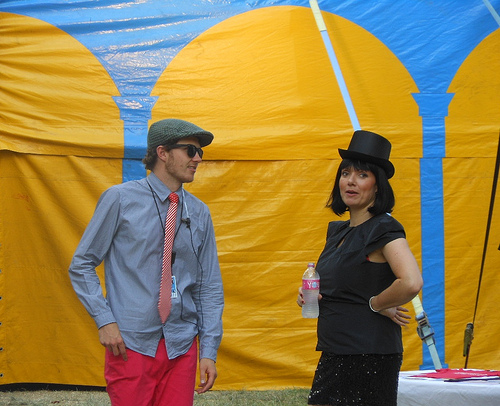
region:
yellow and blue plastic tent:
[1, 0, 499, 392]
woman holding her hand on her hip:
[295, 127, 425, 404]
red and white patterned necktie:
[156, 191, 180, 327]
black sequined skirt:
[306, 349, 405, 404]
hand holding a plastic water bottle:
[296, 260, 324, 320]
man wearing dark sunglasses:
[63, 116, 227, 403]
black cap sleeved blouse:
[312, 213, 409, 353]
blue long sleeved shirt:
[63, 170, 226, 365]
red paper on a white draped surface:
[397, 364, 499, 404]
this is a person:
[89, 123, 246, 397]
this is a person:
[309, 140, 450, 400]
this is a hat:
[138, 115, 218, 145]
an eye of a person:
[354, 168, 385, 183]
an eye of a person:
[330, 160, 357, 185]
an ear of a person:
[150, 139, 175, 173]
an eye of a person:
[181, 155, 200, 177]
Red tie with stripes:
[154, 189, 184, 327]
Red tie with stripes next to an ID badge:
[146, 182, 188, 323]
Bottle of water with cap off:
[278, 247, 329, 317]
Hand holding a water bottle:
[295, 250, 325, 322]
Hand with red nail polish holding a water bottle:
[290, 260, 331, 318]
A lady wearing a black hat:
[301, 107, 401, 222]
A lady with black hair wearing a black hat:
[301, 120, 402, 230]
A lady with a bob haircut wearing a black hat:
[311, 111, 401, 223]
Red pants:
[80, 295, 207, 400]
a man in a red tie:
[77, 117, 233, 393]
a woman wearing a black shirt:
[308, 134, 408, 371]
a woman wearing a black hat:
[311, 130, 416, 400]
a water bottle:
[302, 262, 320, 318]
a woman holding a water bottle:
[300, 133, 414, 394]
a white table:
[406, 358, 495, 403]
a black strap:
[456, 156, 499, 361]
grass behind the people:
[215, 386, 307, 403]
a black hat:
[335, 129, 397, 182]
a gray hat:
[142, 120, 214, 152]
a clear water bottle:
[302, 263, 322, 318]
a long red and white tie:
[155, 190, 183, 322]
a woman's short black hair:
[321, 158, 400, 220]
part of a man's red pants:
[101, 340, 200, 405]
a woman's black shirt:
[312, 214, 417, 359]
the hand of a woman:
[376, 301, 413, 329]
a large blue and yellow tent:
[0, 0, 496, 386]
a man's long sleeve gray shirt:
[69, 173, 226, 362]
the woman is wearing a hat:
[337, 127, 399, 175]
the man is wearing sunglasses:
[158, 140, 204, 160]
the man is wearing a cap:
[145, 117, 213, 157]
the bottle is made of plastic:
[303, 262, 318, 313]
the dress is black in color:
[318, 215, 409, 400]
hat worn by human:
[143, 119, 214, 151]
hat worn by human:
[339, 127, 397, 179]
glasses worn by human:
[165, 140, 202, 160]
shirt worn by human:
[69, 168, 223, 358]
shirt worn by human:
[314, 208, 407, 354]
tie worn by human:
[157, 191, 179, 323]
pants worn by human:
[104, 322, 200, 404]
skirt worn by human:
[307, 336, 401, 404]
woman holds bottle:
[301, 260, 321, 318]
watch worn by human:
[368, 294, 380, 311]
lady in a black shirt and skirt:
[296, 132, 426, 404]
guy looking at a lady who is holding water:
[64, 116, 431, 404]